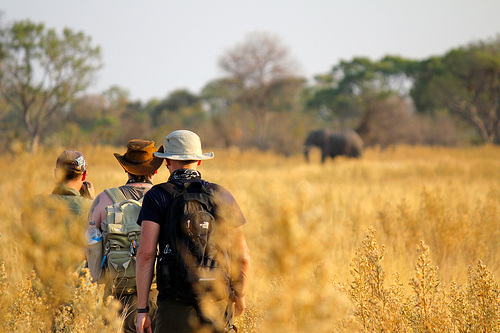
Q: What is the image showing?
A: It is showing a plain.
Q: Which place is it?
A: It is a plain.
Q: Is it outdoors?
A: Yes, it is outdoors.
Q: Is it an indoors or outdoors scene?
A: It is outdoors.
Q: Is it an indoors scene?
A: No, it is outdoors.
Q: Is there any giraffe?
A: No, there are no giraffes.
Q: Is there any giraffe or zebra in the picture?
A: No, there are no giraffes or zebras.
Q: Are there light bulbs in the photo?
A: No, there are no light bulbs.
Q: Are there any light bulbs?
A: No, there are no light bulbs.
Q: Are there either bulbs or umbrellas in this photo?
A: No, there are no bulbs or umbrellas.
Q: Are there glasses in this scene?
A: No, there are no glasses.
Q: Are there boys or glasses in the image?
A: No, there are no glasses or boys.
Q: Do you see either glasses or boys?
A: No, there are no glasses or boys.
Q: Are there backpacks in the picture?
A: Yes, there is a backpack.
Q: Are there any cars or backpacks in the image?
A: Yes, there is a backpack.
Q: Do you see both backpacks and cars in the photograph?
A: No, there is a backpack but no cars.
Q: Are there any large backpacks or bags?
A: Yes, there is a large backpack.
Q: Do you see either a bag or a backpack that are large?
A: Yes, the backpack is large.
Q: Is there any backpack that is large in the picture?
A: Yes, there is a large backpack.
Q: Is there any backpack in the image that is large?
A: Yes, there is a large backpack.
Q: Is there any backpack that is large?
A: Yes, there is a backpack that is large.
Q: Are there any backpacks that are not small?
A: Yes, there is a large backpack.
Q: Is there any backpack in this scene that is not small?
A: Yes, there is a large backpack.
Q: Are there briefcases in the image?
A: No, there are no briefcases.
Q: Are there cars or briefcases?
A: No, there are no briefcases or cars.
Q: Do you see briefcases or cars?
A: No, there are no briefcases or cars.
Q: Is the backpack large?
A: Yes, the backpack is large.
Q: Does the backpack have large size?
A: Yes, the backpack is large.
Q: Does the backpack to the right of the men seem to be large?
A: Yes, the backpack is large.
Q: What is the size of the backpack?
A: The backpack is large.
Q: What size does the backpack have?
A: The backpack has large size.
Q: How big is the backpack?
A: The backpack is large.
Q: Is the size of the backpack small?
A: No, the backpack is large.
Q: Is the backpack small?
A: No, the backpack is large.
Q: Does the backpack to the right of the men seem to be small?
A: No, the backpack is large.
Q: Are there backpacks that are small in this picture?
A: No, there is a backpack but it is large.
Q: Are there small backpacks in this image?
A: No, there is a backpack but it is large.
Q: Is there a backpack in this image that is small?
A: No, there is a backpack but it is large.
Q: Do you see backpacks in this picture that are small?
A: No, there is a backpack but it is large.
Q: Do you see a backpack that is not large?
A: No, there is a backpack but it is large.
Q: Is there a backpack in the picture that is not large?
A: No, there is a backpack but it is large.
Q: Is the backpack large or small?
A: The backpack is large.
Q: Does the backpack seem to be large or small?
A: The backpack is large.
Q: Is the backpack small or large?
A: The backpack is large.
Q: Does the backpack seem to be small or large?
A: The backpack is large.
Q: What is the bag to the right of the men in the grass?
A: The bag is a backpack.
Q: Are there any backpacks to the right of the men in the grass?
A: Yes, there is a backpack to the right of the men.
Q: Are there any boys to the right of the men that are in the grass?
A: No, there is a backpack to the right of the men.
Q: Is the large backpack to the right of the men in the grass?
A: Yes, the backpack is to the right of the men.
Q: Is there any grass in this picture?
A: Yes, there is grass.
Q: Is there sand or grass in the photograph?
A: Yes, there is grass.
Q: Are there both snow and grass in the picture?
A: No, there is grass but no snow.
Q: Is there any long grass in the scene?
A: Yes, there is long grass.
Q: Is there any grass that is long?
A: Yes, there is grass that is long.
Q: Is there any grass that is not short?
A: Yes, there is long grass.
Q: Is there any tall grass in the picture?
A: Yes, there is tall grass.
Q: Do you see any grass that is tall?
A: Yes, there is grass that is tall.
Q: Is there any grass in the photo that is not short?
A: Yes, there is tall grass.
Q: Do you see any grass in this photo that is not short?
A: Yes, there is tall grass.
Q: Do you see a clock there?
A: No, there are no clocks.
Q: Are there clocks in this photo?
A: No, there are no clocks.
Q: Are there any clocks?
A: No, there are no clocks.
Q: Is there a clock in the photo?
A: No, there are no clocks.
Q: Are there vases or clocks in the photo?
A: No, there are no clocks or vases.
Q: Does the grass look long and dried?
A: Yes, the grass is long and dried.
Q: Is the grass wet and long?
A: No, the grass is long but dried.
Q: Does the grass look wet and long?
A: No, the grass is long but dried.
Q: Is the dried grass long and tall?
A: Yes, the grass is long and tall.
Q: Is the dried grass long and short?
A: No, the grass is long but tall.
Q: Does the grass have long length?
A: Yes, the grass is long.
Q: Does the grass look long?
A: Yes, the grass is long.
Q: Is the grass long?
A: Yes, the grass is long.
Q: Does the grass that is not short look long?
A: Yes, the grass is long.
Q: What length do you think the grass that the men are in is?
A: The grass is long.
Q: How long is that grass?
A: The grass is long.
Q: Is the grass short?
A: No, the grass is long.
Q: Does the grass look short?
A: No, the grass is long.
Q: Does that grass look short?
A: No, the grass is long.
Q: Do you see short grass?
A: No, there is grass but it is long.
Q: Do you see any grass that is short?
A: No, there is grass but it is long.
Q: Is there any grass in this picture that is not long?
A: No, there is grass but it is long.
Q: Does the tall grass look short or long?
A: The grass is long.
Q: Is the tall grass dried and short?
A: No, the grass is dried but long.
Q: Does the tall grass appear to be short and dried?
A: No, the grass is dried but long.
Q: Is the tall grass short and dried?
A: No, the grass is dried but long.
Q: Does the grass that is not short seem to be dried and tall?
A: Yes, the grass is dried and tall.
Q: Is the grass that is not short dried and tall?
A: Yes, the grass is dried and tall.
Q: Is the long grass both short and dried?
A: No, the grass is dried but tall.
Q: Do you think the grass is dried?
A: Yes, the grass is dried.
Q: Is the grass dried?
A: Yes, the grass is dried.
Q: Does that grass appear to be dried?
A: Yes, the grass is dried.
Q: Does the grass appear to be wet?
A: No, the grass is dried.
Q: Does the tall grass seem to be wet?
A: No, the grass is dried.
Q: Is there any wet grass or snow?
A: No, there is grass but it is dried.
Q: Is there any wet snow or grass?
A: No, there is grass but it is dried.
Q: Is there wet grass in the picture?
A: No, there is grass but it is dried.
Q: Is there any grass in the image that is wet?
A: No, there is grass but it is dried.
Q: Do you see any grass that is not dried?
A: No, there is grass but it is dried.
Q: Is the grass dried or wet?
A: The grass is dried.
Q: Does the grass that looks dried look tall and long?
A: Yes, the grass is tall and long.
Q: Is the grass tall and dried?
A: Yes, the grass is tall and dried.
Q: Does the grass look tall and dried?
A: Yes, the grass is tall and dried.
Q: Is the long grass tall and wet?
A: No, the grass is tall but dried.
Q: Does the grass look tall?
A: Yes, the grass is tall.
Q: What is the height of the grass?
A: The grass is tall.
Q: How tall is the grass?
A: The grass is tall.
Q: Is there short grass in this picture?
A: No, there is grass but it is tall.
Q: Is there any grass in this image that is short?
A: No, there is grass but it is tall.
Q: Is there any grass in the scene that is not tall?
A: No, there is grass but it is tall.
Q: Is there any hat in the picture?
A: Yes, there is a hat.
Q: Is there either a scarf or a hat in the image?
A: Yes, there is a hat.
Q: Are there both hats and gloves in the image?
A: No, there is a hat but no gloves.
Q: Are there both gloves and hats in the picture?
A: No, there is a hat but no gloves.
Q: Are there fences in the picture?
A: No, there are no fences.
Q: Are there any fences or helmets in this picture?
A: No, there are no fences or helmets.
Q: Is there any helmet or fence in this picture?
A: No, there are no fences or helmets.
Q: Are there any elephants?
A: Yes, there is an elephant.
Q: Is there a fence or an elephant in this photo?
A: Yes, there is an elephant.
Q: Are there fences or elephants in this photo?
A: Yes, there is an elephant.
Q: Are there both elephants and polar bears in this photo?
A: No, there is an elephant but no polar bears.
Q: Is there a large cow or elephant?
A: Yes, there is a large elephant.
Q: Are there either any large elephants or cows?
A: Yes, there is a large elephant.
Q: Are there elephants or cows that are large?
A: Yes, the elephant is large.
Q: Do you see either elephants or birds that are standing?
A: Yes, the elephant is standing.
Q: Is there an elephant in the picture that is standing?
A: Yes, there is an elephant that is standing.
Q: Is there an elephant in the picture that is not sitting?
A: Yes, there is an elephant that is standing.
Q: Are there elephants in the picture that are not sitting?
A: Yes, there is an elephant that is standing.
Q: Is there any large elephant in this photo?
A: Yes, there is a large elephant.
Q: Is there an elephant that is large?
A: Yes, there is an elephant that is large.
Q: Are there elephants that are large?
A: Yes, there is an elephant that is large.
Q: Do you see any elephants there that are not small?
A: Yes, there is a large elephant.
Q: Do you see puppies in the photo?
A: No, there are no puppies.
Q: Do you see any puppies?
A: No, there are no puppies.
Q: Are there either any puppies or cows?
A: No, there are no puppies or cows.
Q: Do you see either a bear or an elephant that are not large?
A: No, there is an elephant but it is large.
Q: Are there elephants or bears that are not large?
A: No, there is an elephant but it is large.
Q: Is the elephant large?
A: Yes, the elephant is large.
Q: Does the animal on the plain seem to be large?
A: Yes, the elephant is large.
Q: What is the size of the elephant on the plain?
A: The elephant is large.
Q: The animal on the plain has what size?
A: The elephant is large.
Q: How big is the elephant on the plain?
A: The elephant is large.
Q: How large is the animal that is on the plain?
A: The elephant is large.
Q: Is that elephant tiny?
A: No, the elephant is large.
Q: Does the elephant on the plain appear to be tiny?
A: No, the elephant is large.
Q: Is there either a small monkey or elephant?
A: No, there is an elephant but it is large.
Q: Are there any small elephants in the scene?
A: No, there is an elephant but it is large.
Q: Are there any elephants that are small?
A: No, there is an elephant but it is large.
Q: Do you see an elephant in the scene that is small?
A: No, there is an elephant but it is large.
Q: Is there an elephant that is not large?
A: No, there is an elephant but it is large.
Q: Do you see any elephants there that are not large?
A: No, there is an elephant but it is large.